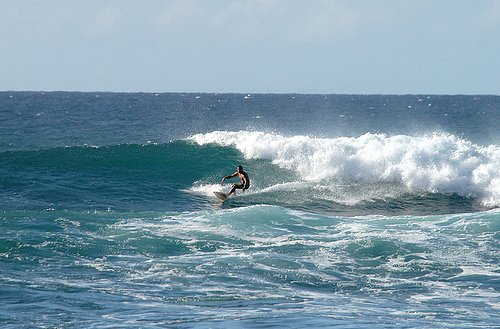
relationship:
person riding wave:
[221, 164, 251, 194] [4, 127, 492, 287]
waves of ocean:
[5, 129, 496, 289] [4, 89, 496, 324]